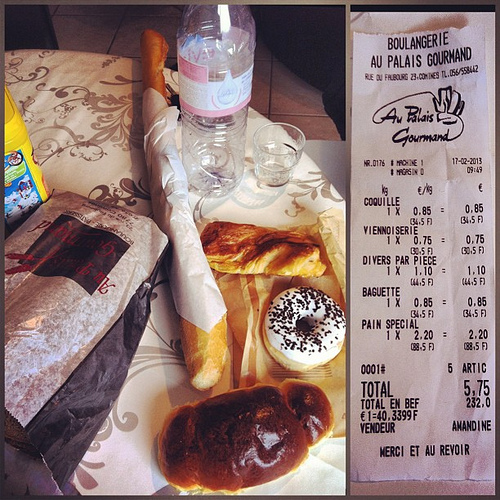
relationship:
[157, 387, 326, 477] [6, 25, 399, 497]
brioche on table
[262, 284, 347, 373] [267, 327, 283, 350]
donut with white glaze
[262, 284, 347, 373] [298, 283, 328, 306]
donut with sprinkles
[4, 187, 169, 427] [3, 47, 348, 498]
bag on table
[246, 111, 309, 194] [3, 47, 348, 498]
glass on table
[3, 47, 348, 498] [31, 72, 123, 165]
table with tablecloth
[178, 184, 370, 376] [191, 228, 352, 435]
pastry on bag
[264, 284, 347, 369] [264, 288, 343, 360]
donut with white icing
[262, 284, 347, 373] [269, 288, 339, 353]
donut with sprinkles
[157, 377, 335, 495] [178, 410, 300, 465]
brioche with top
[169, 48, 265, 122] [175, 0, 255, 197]
label on bottle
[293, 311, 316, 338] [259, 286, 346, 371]
center of donut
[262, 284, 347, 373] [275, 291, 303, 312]
donut with sprinkles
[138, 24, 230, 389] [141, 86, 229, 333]
baguette in paper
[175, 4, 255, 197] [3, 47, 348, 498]
bottle on table